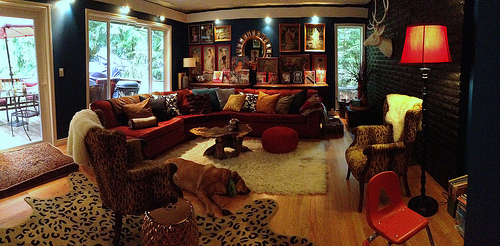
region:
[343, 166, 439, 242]
A red chair.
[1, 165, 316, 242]
A rug with a leopard skin pattern is on the floor.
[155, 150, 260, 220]
The dog is lying down.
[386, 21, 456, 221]
A lamp.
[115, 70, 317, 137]
Different colored pillows are on the couch.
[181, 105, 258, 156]
A small coffee table.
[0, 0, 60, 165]
A door.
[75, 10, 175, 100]
A large window.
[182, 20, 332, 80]
Framed pictures are on the wall.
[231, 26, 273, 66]
A mirror.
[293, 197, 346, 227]
this is the floor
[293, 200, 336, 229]
the floor is wooden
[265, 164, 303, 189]
this is a carpet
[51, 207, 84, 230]
the carpet has an animal print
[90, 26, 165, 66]
this is a window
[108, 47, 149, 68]
the window is made of glass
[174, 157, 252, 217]
this is a dog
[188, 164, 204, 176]
the fur is brown in color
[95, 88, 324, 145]
this is a couch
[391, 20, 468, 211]
this is a lamp shade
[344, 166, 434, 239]
a small red chair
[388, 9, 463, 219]
a tall floor lamp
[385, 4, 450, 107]
the lamp is on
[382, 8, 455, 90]
the lamp has a shade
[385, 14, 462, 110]
the shade is red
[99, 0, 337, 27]
the lights are on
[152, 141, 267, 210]
the dog is laying on the floor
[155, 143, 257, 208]
the dog is light brown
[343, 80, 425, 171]
a leopard print chair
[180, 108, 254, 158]
a wooden coffee table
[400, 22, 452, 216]
standing pole lamp with red lamp shade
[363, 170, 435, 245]
red chair with hole in back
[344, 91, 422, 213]
leopard print arm chair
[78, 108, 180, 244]
leopard print wing back chair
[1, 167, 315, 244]
leopard print animal skin rug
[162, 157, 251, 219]
a dog sleeping on the floor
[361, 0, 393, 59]
a deer head on the wall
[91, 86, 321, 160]
a red sectional couch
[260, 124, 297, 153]
a round red ottoman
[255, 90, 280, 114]
yellow throw pillow on couch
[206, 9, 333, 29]
three lights on wall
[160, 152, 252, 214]
dog sleeping on floor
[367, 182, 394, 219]
triangle on red chair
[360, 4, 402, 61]
animal with antlers on wall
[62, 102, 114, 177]
blanket on back of chair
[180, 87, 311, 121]
decorative pillows on couch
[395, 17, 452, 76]
glowing red lamp shade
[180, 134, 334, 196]
furry white rug on floor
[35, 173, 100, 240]
animal print rug on floor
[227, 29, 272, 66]
round mirror on wall